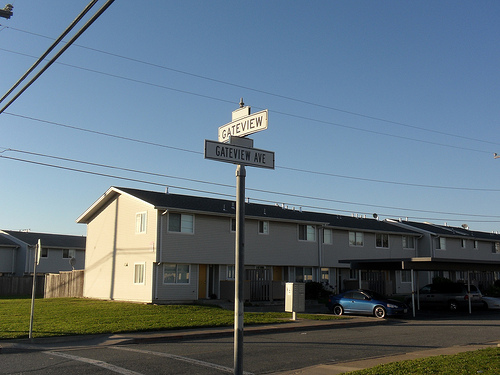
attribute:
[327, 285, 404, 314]
car — small, blue, parked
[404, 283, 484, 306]
van — big, brown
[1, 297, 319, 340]
grass — healthy, green, on front lawn, on lawn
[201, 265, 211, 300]
door — bright yellow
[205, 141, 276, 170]
sign — gateview ave, white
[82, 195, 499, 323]
house — nice, big, tan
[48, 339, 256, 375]
stripes — white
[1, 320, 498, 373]
road — black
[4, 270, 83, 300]
fence — old, wooden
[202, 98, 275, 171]
signs — white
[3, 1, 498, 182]
sky — clear, blue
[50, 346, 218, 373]
lines — white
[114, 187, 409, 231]
roof — black